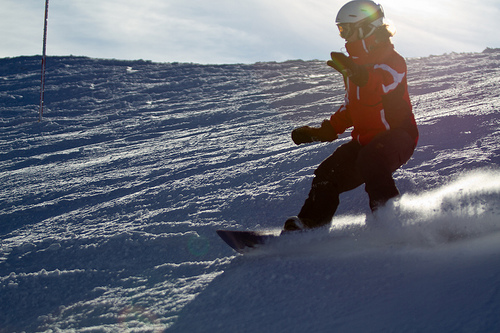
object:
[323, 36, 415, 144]
jacket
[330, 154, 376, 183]
black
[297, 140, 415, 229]
pants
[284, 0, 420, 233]
snowboarder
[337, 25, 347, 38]
lenses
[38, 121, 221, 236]
lines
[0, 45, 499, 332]
snow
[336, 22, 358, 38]
goggles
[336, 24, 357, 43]
face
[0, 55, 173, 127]
hill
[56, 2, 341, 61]
cloudy sky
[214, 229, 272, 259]
snowboard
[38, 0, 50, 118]
pole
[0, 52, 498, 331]
ground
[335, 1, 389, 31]
train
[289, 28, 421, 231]
uniform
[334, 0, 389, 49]
head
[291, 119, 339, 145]
glove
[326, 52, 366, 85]
glove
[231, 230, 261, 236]
part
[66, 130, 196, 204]
track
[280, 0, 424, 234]
person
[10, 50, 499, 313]
snowy slope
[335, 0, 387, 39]
helmet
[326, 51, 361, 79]
hand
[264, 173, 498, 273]
air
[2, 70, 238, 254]
snow surface